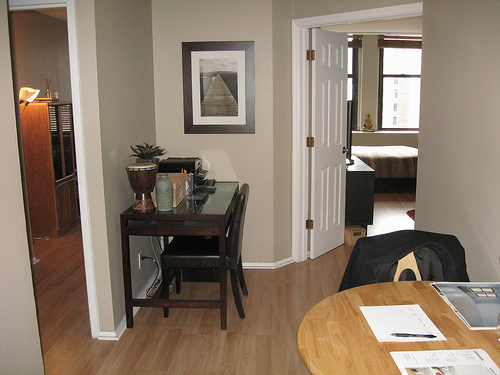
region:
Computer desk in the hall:
[125, 139, 259, 331]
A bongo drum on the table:
[122, 155, 161, 223]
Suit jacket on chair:
[330, 217, 472, 294]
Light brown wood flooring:
[162, 325, 196, 370]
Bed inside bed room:
[352, 130, 440, 177]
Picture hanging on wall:
[175, 42, 257, 132]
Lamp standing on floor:
[14, 81, 54, 273]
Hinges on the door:
[299, 41, 324, 261]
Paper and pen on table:
[358, 290, 450, 357]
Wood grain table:
[330, 303, 351, 373]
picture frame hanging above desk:
[168, 26, 271, 165]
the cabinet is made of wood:
[16, 94, 114, 239]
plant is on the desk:
[123, 127, 186, 203]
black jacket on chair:
[326, 207, 496, 318]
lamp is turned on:
[10, 73, 43, 113]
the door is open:
[296, 26, 354, 253]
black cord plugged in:
[133, 248, 178, 305]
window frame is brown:
[369, 30, 426, 154]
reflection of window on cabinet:
[41, 97, 79, 131]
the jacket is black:
[319, 212, 491, 321]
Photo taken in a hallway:
[0, 0, 491, 367]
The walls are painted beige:
[3, 32, 495, 282]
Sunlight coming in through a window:
[355, 29, 440, 139]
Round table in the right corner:
[277, 270, 499, 371]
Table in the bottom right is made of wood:
[282, 262, 499, 369]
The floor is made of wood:
[27, 203, 450, 373]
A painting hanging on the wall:
[159, 27, 269, 140]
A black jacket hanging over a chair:
[312, 215, 482, 285]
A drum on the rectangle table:
[130, 159, 164, 214]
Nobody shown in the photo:
[8, 5, 493, 370]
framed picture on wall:
[179, 38, 256, 138]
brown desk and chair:
[116, 175, 253, 333]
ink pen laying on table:
[388, 328, 439, 340]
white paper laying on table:
[358, 298, 448, 345]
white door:
[308, 25, 351, 260]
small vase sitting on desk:
[154, 169, 174, 215]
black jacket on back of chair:
[337, 226, 471, 291]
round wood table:
[294, 274, 498, 373]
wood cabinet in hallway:
[15, 96, 81, 238]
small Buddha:
[360, 113, 377, 133]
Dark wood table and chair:
[112, 138, 255, 331]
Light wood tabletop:
[291, 276, 471, 371]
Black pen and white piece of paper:
[355, 291, 446, 351]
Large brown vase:
[120, 155, 162, 212]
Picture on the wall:
[160, 25, 265, 140]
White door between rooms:
[298, 22, 358, 259]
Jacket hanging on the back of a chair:
[332, 226, 472, 292]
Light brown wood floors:
[141, 328, 226, 370]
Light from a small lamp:
[15, 82, 36, 105]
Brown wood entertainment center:
[18, 96, 81, 255]